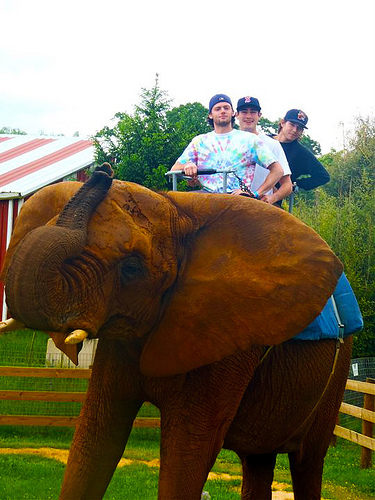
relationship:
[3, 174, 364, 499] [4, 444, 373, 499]
elephant standing on dirt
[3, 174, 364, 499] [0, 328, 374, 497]
elephant standing on grass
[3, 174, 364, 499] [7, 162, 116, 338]
elephant has trunk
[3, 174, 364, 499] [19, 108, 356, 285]
elephant in wooden enclosure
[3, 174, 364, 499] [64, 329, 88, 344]
elephant has elephant tusk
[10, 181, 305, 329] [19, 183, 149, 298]
elephant has trunk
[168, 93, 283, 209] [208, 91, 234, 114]
boy has blue cap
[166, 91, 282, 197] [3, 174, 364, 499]
guy riding elephant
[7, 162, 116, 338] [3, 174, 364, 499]
trunk of elephant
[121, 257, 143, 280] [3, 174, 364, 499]
eye of elephant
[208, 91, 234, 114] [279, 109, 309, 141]
blue cap on head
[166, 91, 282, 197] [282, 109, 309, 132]
guy with hat